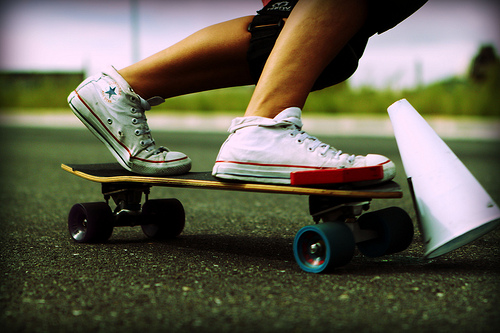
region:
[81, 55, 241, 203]
person wears white shoes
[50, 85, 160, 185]
shoes have red stripe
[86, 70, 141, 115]
blue logo star on shoe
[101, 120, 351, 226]
person on black skateboard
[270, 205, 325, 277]
skateboard has blue wheel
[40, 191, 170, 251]
skateboard has black wheels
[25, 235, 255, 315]
skateboard on black concrete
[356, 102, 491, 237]
skateboard near white cone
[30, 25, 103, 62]
sky is grey and overcast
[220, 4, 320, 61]
person wears dark shorts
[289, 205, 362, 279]
Blue and red skateboard wheel.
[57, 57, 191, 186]
Red and white converse.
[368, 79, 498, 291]
White cone.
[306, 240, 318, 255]
Screw holding wheel in place.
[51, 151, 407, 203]
Black skateboard.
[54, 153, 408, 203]
Brown trim on skateboard.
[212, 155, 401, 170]
Red trim on white shoe.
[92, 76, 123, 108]
Logo with star on shoe.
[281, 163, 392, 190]
Red square object.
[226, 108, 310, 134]
Shoe laces tied around back of shoe.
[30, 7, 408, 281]
a person is skateboarding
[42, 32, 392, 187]
the sneakers are white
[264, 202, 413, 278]
the wheels are blue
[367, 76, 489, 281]
a cone on the street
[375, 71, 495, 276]
the cone is white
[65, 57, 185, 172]
the left foot heel is up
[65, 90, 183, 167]
red line around the base of the sneaker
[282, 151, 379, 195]
a red object next to the foot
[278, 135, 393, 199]
an object on top of the skateboard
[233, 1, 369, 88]
the person is wearing a knee brace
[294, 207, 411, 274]
blue wheels on the front of the skateboard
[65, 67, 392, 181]
white Converse tennishoes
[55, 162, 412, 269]
skateboard with mismatched wheels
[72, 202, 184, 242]
two dark red back skateboard wheels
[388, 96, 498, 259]
white rubber cone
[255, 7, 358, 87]
knee pad on the skateboarder's left knee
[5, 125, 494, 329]
green artificial turn surface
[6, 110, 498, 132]
gray sidewalk in the distance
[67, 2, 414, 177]
a skateboarder's legs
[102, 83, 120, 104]
Blue star of Converse logo on shoe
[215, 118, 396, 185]
His shoes are white.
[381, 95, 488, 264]
The megaphone is white.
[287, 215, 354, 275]
The wheel is blue.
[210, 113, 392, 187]
One foot planted on the skateboard.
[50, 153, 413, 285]
The skateboard is black.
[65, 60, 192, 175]
One foot is leaning on the board.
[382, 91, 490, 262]
The megaphone is leaning.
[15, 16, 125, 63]
The sky is clear.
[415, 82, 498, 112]
The grass is green.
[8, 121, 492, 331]
He is riding a skateboard.